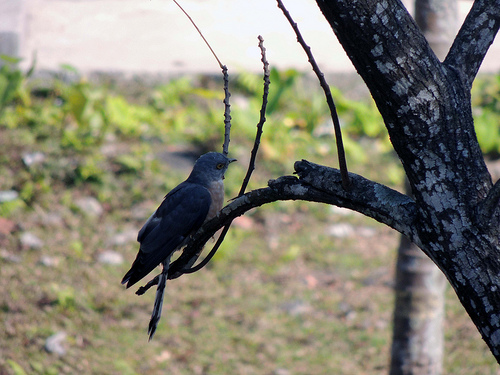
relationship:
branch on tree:
[251, 34, 273, 191] [136, 1, 498, 364]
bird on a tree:
[121, 149, 240, 286] [136, 1, 498, 364]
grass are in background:
[0, 187, 500, 374] [39, 73, 214, 143]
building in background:
[19, 0, 498, 70] [15, 9, 445, 62]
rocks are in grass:
[21, 189, 145, 262] [0, 147, 500, 373]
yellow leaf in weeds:
[275, 112, 297, 132] [1, 52, 498, 209]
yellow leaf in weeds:
[257, 135, 281, 164] [1, 52, 498, 209]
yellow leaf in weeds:
[311, 139, 332, 158] [1, 52, 498, 209]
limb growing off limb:
[442, 2, 497, 81] [329, 3, 451, 183]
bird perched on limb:
[121, 149, 240, 286] [136, 176, 301, 298]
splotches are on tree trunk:
[394, 76, 466, 224] [380, 131, 493, 294]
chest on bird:
[208, 195, 219, 221] [132, 150, 235, 318]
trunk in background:
[382, 172, 475, 374] [239, 201, 497, 361]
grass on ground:
[77, 50, 242, 145] [9, 124, 487, 373]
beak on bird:
[223, 153, 238, 166] [121, 150, 240, 291]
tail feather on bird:
[119, 252, 151, 286] [121, 150, 240, 291]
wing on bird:
[139, 183, 207, 253] [104, 142, 256, 287]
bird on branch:
[121, 150, 240, 291] [126, 155, 416, 334]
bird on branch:
[121, 150, 240, 291] [157, 186, 317, 274]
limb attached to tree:
[442, 2, 497, 81] [136, 1, 498, 364]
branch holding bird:
[134, 159, 419, 295] [141, 142, 240, 347]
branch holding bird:
[134, 157, 431, 295] [121, 149, 240, 286]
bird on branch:
[121, 150, 240, 291] [224, 12, 425, 215]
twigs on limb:
[138, 5, 363, 247] [139, 156, 415, 295]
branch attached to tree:
[134, 159, 419, 295] [136, 1, 498, 364]